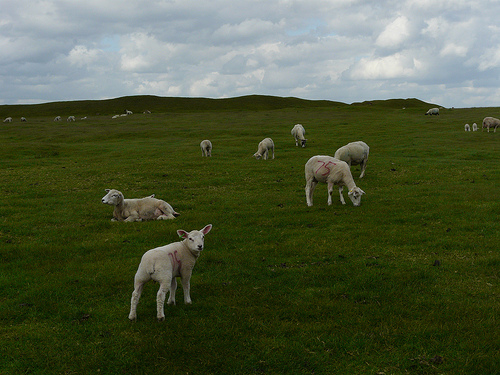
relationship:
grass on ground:
[2, 102, 498, 372] [203, 190, 476, 345]